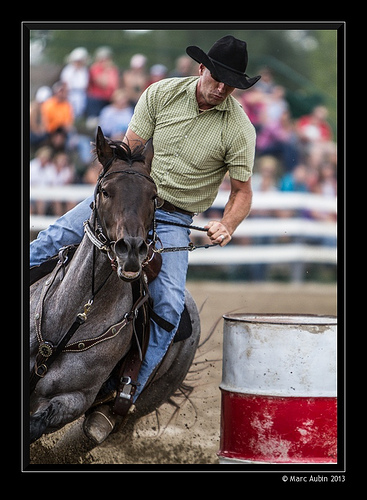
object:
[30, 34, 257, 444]
man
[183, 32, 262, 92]
hat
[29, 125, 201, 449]
horse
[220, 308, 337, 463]
drum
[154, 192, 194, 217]
belt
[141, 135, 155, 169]
ear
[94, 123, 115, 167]
ear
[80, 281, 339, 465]
ground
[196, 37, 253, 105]
head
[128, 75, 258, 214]
shirt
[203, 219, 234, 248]
hand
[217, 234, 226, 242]
ring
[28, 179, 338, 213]
rail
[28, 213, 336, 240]
rail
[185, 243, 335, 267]
rail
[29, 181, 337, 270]
fence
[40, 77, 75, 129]
spectators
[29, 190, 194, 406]
jeans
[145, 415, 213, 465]
dirt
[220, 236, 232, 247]
finger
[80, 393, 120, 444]
boot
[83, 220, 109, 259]
straps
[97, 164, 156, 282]
horse face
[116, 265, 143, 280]
mouth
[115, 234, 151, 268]
nose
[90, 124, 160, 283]
horse head